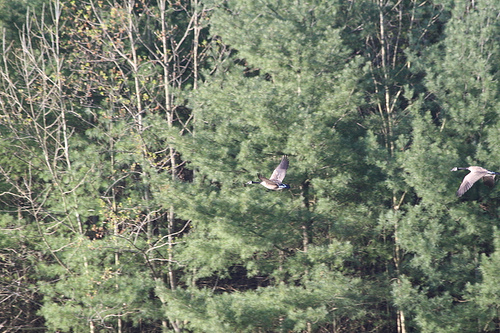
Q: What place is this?
A: It is a forest.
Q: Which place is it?
A: It is a forest.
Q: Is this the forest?
A: Yes, it is the forest.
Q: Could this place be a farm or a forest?
A: It is a forest.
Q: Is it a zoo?
A: No, it is a forest.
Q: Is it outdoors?
A: Yes, it is outdoors.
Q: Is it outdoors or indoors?
A: It is outdoors.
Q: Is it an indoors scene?
A: No, it is outdoors.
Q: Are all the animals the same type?
A: No, there are both geese and birds.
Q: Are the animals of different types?
A: Yes, they are geese and birds.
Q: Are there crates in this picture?
A: No, there are no crates.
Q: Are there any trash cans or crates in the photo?
A: No, there are no crates or trash cans.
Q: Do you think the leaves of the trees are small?
A: Yes, the leaves are small.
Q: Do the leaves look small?
A: Yes, the leaves are small.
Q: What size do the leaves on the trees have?
A: The leaves have small size.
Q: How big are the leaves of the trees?
A: The leaves are small.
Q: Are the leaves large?
A: No, the leaves are small.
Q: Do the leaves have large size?
A: No, the leaves are small.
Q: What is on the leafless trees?
A: The leaves are on the trees.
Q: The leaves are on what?
A: The leaves are on the trees.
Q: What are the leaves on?
A: The leaves are on the trees.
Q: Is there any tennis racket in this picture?
A: No, there are no rackets.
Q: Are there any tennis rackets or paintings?
A: No, there are no tennis rackets or paintings.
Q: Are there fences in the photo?
A: No, there are no fences.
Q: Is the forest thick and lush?
A: Yes, the forest is thick and lush.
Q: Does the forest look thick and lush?
A: Yes, the forest is thick and lush.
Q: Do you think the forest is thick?
A: Yes, the forest is thick.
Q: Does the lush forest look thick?
A: Yes, the forest is thick.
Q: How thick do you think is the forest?
A: The forest is thick.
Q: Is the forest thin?
A: No, the forest is thick.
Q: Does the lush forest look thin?
A: No, the forest is thick.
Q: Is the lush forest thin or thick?
A: The forest is thick.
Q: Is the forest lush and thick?
A: Yes, the forest is lush and thick.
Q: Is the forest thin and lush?
A: No, the forest is lush but thick.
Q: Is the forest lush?
A: Yes, the forest is lush.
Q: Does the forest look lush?
A: Yes, the forest is lush.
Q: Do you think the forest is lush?
A: Yes, the forest is lush.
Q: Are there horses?
A: No, there are no horses.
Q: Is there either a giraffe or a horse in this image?
A: No, there are no horses or giraffes.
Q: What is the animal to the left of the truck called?
A: The animal is a goose.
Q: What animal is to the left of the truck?
A: The animal is a goose.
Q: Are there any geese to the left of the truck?
A: Yes, there is a goose to the left of the truck.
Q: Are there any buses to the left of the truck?
A: No, there is a goose to the left of the truck.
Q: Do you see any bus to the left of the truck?
A: No, there is a goose to the left of the truck.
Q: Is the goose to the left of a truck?
A: Yes, the goose is to the left of a truck.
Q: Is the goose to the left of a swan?
A: No, the goose is to the left of a truck.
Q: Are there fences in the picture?
A: No, there are no fences.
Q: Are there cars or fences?
A: No, there are no fences or cars.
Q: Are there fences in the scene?
A: No, there are no fences.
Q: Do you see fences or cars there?
A: No, there are no fences or cars.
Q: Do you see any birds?
A: Yes, there are birds.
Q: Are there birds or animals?
A: Yes, there are birds.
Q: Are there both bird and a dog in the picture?
A: No, there are birds but no dogs.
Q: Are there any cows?
A: No, there are no cows.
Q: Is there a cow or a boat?
A: No, there are no cows or boats.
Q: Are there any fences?
A: No, there are no fences.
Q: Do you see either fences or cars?
A: No, there are no fences or cars.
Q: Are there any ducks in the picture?
A: Yes, there is a duck.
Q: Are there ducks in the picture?
A: Yes, there is a duck.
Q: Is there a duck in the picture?
A: Yes, there is a duck.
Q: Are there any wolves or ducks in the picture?
A: Yes, there is a duck.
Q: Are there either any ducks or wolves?
A: Yes, there is a duck.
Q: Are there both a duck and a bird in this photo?
A: Yes, there are both a duck and a bird.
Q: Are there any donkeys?
A: No, there are no donkeys.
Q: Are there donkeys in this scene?
A: No, there are no donkeys.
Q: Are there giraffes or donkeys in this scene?
A: No, there are no donkeys or giraffes.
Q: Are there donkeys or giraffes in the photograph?
A: No, there are no donkeys or giraffes.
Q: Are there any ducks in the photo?
A: Yes, there is a duck.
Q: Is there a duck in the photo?
A: Yes, there is a duck.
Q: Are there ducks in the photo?
A: Yes, there is a duck.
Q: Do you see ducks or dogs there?
A: Yes, there is a duck.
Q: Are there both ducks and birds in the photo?
A: Yes, there are both a duck and a bird.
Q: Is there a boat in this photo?
A: No, there are no boats.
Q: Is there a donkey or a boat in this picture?
A: No, there are no boats or donkeys.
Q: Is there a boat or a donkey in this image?
A: No, there are no boats or donkeys.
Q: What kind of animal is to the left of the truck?
A: The animal is a duck.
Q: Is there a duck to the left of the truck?
A: Yes, there is a duck to the left of the truck.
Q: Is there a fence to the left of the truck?
A: No, there is a duck to the left of the truck.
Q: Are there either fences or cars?
A: No, there are no fences or cars.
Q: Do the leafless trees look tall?
A: Yes, the trees are tall.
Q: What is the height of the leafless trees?
A: The trees are tall.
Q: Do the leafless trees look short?
A: No, the trees are tall.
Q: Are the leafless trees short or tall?
A: The trees are tall.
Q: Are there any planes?
A: No, there are no planes.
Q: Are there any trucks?
A: Yes, there is a truck.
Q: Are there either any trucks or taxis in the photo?
A: Yes, there is a truck.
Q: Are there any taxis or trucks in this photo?
A: Yes, there is a truck.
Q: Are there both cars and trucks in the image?
A: No, there is a truck but no cars.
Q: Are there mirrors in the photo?
A: No, there are no mirrors.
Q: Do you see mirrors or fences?
A: No, there are no mirrors or fences.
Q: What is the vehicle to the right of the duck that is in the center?
A: The vehicle is a truck.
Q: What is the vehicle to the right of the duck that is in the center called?
A: The vehicle is a truck.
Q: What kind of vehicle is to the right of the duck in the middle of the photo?
A: The vehicle is a truck.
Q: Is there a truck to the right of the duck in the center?
A: Yes, there is a truck to the right of the duck.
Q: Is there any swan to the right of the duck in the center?
A: No, there is a truck to the right of the duck.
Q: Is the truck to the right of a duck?
A: Yes, the truck is to the right of a duck.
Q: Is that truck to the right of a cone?
A: No, the truck is to the right of a duck.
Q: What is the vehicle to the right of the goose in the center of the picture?
A: The vehicle is a truck.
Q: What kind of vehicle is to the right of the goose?
A: The vehicle is a truck.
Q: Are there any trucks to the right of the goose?
A: Yes, there is a truck to the right of the goose.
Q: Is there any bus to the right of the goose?
A: No, there is a truck to the right of the goose.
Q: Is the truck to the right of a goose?
A: Yes, the truck is to the right of a goose.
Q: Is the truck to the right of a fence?
A: No, the truck is to the right of a goose.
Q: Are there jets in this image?
A: No, there are no jets.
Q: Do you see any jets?
A: No, there are no jets.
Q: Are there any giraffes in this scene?
A: No, there are no giraffes.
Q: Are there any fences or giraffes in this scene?
A: No, there are no giraffes or fences.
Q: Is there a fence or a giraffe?
A: No, there are no giraffes or fences.